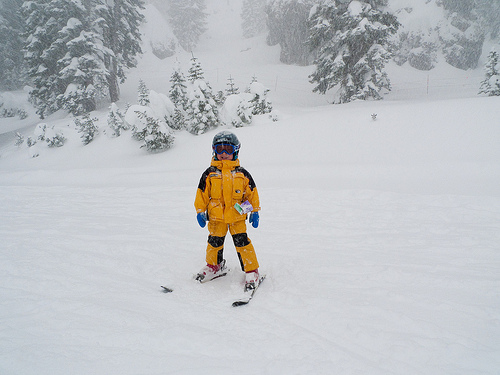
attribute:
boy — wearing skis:
[192, 129, 262, 280]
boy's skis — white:
[161, 268, 265, 308]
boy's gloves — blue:
[194, 211, 261, 228]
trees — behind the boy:
[1, 4, 473, 133]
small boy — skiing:
[193, 130, 263, 286]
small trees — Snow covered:
[6, 2, 417, 114]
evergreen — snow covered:
[0, 0, 428, 118]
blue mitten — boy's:
[247, 208, 260, 227]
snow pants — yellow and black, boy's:
[206, 220, 256, 274]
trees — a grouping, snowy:
[2, 6, 367, 106]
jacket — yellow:
[196, 160, 260, 220]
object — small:
[366, 109, 384, 126]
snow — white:
[266, 80, 496, 345]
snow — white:
[288, 129, 491, 349]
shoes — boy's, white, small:
[193, 262, 270, 291]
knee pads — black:
[208, 233, 251, 248]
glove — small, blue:
[193, 214, 209, 231]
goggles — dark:
[209, 140, 238, 157]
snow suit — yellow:
[190, 150, 271, 273]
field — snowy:
[0, 95, 494, 365]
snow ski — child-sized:
[229, 268, 267, 312]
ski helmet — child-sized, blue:
[207, 121, 241, 155]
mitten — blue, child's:
[248, 209, 260, 227]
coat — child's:
[190, 159, 263, 239]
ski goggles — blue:
[210, 138, 240, 157]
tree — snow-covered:
[300, 3, 399, 104]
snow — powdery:
[1, 67, 498, 373]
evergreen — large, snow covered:
[17, 8, 150, 118]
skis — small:
[159, 261, 229, 295]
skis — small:
[233, 269, 269, 310]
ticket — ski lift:
[230, 198, 254, 218]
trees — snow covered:
[17, 2, 148, 118]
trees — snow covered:
[298, 4, 404, 105]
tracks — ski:
[4, 165, 498, 372]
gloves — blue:
[197, 209, 210, 225]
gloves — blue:
[245, 209, 263, 228]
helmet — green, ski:
[209, 124, 247, 157]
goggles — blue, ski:
[211, 135, 243, 159]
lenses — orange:
[214, 139, 233, 154]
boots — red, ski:
[195, 259, 226, 282]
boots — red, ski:
[242, 271, 265, 291]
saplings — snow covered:
[165, 51, 225, 137]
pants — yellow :
[170, 225, 309, 278]